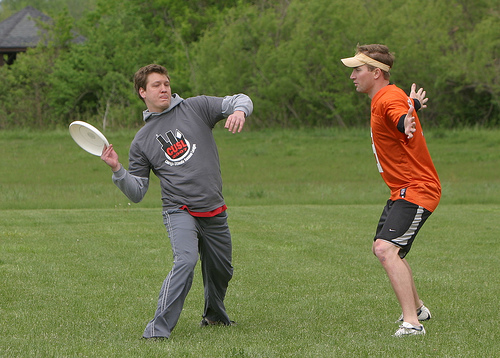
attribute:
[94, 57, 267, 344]
man — offense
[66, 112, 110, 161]
frisbee — plastic, white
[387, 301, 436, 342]
shoes — black, white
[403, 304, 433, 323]
right shoe — black, white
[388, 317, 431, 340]
left shoe — black, white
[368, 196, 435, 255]
shorts — black, grey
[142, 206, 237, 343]
pants — grey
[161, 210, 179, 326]
stripe — white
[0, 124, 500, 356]
grass — green, short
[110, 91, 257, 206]
sweater — grey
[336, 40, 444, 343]
man — blocking, defense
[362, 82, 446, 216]
shirt — orange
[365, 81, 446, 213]
jersey — orange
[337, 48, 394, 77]
visor — tan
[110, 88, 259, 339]
sweatsuit — gray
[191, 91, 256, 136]
left arm — bent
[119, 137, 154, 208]
right arm — bent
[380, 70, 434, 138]
arms — spread